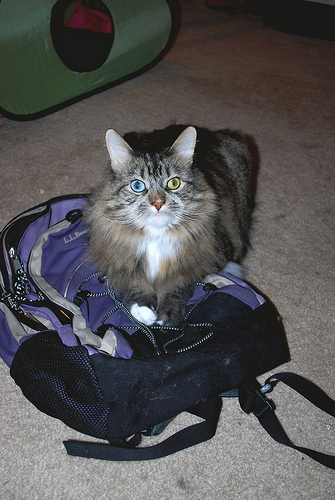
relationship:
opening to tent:
[46, 2, 123, 83] [2, 2, 196, 140]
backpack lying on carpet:
[20, 199, 286, 403] [4, 46, 331, 395]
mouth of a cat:
[149, 208, 171, 218] [81, 120, 262, 325]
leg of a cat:
[113, 259, 159, 322] [96, 125, 225, 246]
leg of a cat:
[147, 287, 179, 322] [96, 125, 225, 246]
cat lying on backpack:
[81, 120, 262, 325] [13, 203, 273, 332]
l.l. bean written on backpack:
[61, 224, 96, 241] [0, 189, 335, 468]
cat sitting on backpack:
[81, 120, 262, 325] [0, 192, 334, 470]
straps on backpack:
[248, 363, 333, 452] [0, 192, 334, 470]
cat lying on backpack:
[81, 122, 253, 328] [0, 189, 335, 468]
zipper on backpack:
[6, 248, 31, 270] [9, 192, 295, 442]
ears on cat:
[104, 125, 201, 170] [86, 123, 262, 294]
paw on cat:
[115, 286, 167, 326] [81, 112, 267, 315]